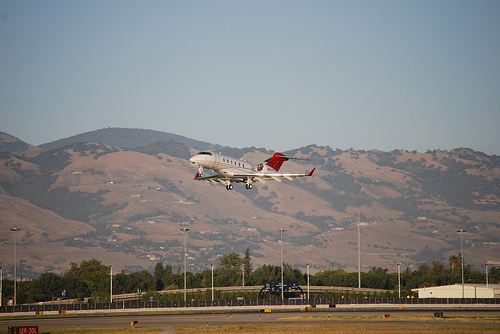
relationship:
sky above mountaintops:
[5, 7, 498, 152] [0, 121, 497, 189]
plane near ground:
[184, 149, 316, 191] [1, 304, 497, 331]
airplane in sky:
[186, 143, 318, 191] [5, 1, 492, 138]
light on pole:
[179, 222, 193, 235] [176, 222, 193, 318]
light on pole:
[449, 230, 471, 237] [460, 237, 463, 297]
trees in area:
[7, 254, 487, 320] [3, 285, 492, 332]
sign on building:
[239, 266, 321, 307] [409, 277, 485, 306]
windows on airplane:
[196, 149, 213, 156] [187, 150, 315, 191]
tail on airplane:
[260, 150, 295, 172] [158, 114, 389, 217]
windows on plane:
[218, 154, 250, 166] [166, 133, 373, 232]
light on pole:
[7, 223, 26, 235] [10, 232, 20, 306]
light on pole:
[180, 227, 189, 232] [180, 232, 190, 304]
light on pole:
[207, 259, 217, 268] [207, 267, 217, 299]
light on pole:
[273, 225, 289, 234] [275, 230, 288, 303]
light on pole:
[457, 229, 467, 232] [455, 232, 467, 304]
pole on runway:
[10, 232, 20, 306] [1, 305, 499, 326]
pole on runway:
[180, 232, 190, 304] [1, 305, 499, 326]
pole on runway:
[207, 267, 217, 299] [1, 305, 499, 326]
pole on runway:
[275, 230, 288, 303] [1, 305, 499, 326]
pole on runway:
[455, 232, 467, 304] [1, 305, 499, 326]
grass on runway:
[4, 281, 492, 332] [2, 300, 483, 331]